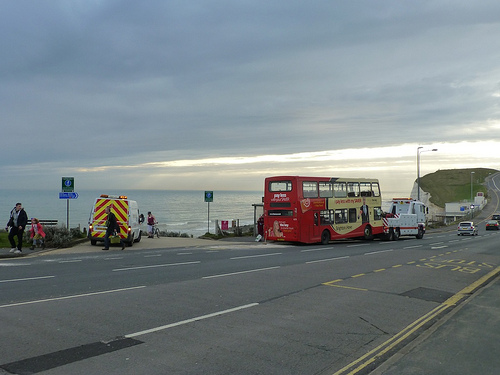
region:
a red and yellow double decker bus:
[262, 166, 382, 246]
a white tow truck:
[376, 195, 428, 241]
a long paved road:
[7, 170, 498, 366]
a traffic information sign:
[56, 172, 79, 229]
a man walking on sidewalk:
[4, 195, 30, 255]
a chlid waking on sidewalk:
[24, 212, 50, 249]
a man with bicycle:
[145, 205, 161, 239]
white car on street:
[454, 219, 474, 233]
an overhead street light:
[411, 142, 443, 202]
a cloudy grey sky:
[3, 1, 483, 166]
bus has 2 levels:
[269, 151, 389, 236]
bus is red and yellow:
[253, 160, 388, 241]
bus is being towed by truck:
[253, 168, 433, 256]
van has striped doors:
[90, 187, 140, 242]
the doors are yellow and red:
[93, 200, 140, 245]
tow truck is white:
[384, 194, 439, 249]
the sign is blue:
[53, 185, 92, 200]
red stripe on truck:
[385, 214, 430, 239]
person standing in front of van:
[140, 201, 170, 236]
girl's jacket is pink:
[21, 214, 46, 244]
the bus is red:
[237, 164, 391, 256]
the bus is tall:
[252, 157, 395, 256]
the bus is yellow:
[263, 163, 391, 254]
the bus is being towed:
[247, 165, 390, 253]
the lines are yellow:
[347, 320, 420, 373]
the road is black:
[157, 292, 218, 311]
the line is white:
[98, 278, 293, 360]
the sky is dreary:
[36, 37, 316, 135]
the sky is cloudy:
[85, 21, 372, 125]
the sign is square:
[199, 187, 215, 204]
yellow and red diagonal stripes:
[91, 190, 130, 243]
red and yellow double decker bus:
[258, 169, 389, 239]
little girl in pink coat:
[28, 210, 46, 251]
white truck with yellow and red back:
[91, 190, 146, 244]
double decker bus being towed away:
[264, 170, 438, 250]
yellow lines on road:
[324, 247, 499, 372]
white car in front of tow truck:
[453, 215, 475, 237]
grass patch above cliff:
[401, 164, 499, 221]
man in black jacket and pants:
[6, 200, 30, 253]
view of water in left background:
[0, 183, 412, 234]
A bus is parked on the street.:
[245, 167, 397, 252]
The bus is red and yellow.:
[248, 167, 388, 250]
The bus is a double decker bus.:
[249, 164, 390, 256]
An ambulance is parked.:
[78, 182, 158, 256]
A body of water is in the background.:
[0, 174, 280, 244]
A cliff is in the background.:
[392, 158, 489, 228]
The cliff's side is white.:
[406, 177, 450, 231]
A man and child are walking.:
[2, 194, 54, 258]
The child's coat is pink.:
[24, 213, 51, 245]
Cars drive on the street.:
[449, 196, 499, 242]